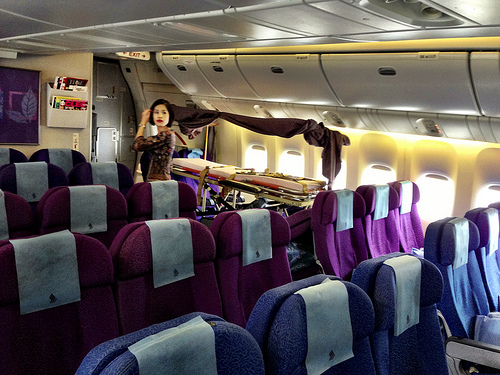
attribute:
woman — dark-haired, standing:
[138, 75, 182, 183]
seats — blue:
[147, 183, 498, 372]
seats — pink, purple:
[20, 131, 462, 339]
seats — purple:
[10, 140, 130, 182]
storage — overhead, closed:
[164, 37, 497, 115]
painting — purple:
[3, 68, 52, 149]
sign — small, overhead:
[110, 47, 164, 71]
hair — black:
[149, 104, 178, 130]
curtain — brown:
[166, 92, 350, 176]